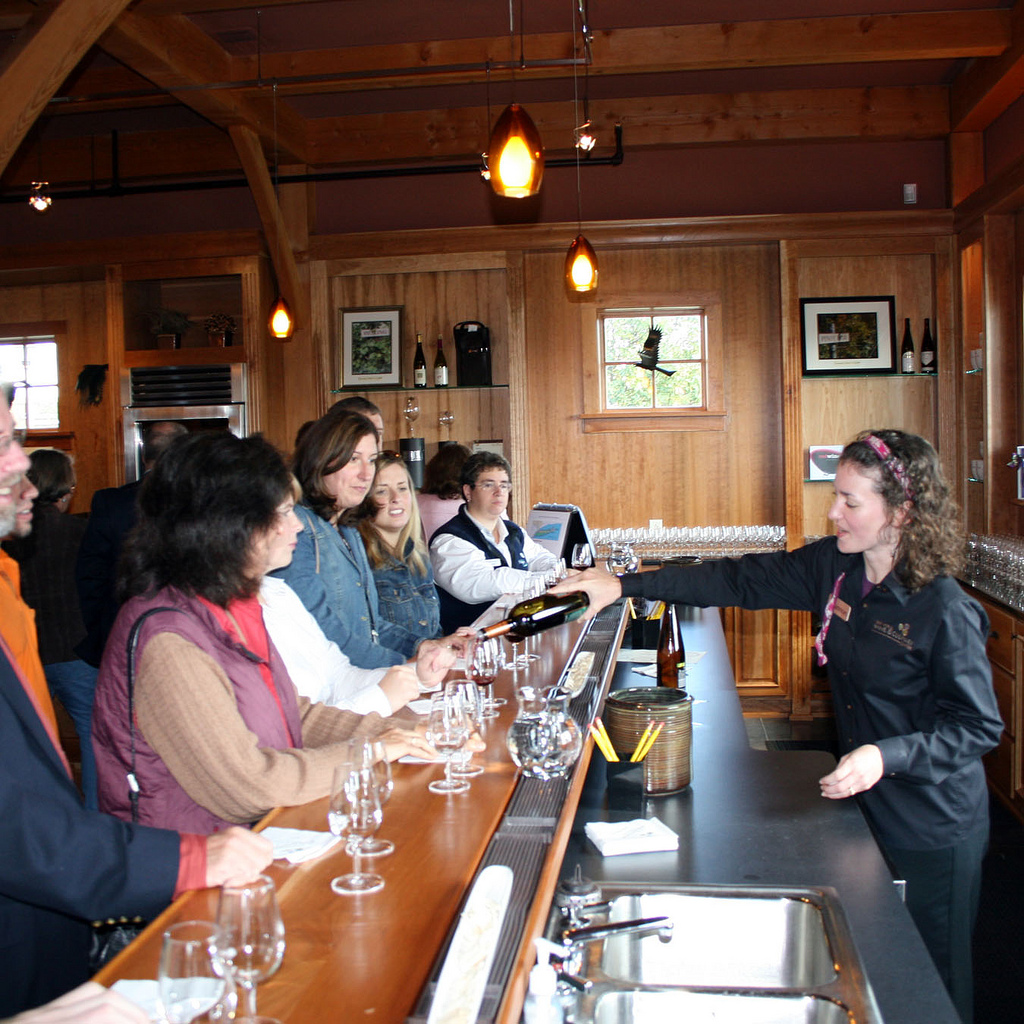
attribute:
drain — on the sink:
[557, 860, 603, 912]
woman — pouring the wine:
[546, 430, 990, 915]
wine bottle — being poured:
[457, 584, 592, 645]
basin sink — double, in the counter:
[570, 873, 880, 1020]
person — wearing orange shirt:
[0, 374, 266, 1007]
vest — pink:
[82, 590, 316, 843]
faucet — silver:
[563, 904, 669, 952]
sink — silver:
[529, 860, 890, 1020]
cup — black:
[604, 755, 646, 808]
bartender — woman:
[534, 402, 1021, 971]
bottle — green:
[464, 589, 598, 652]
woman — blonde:
[374, 443, 448, 647]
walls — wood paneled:
[17, 280, 1022, 682]